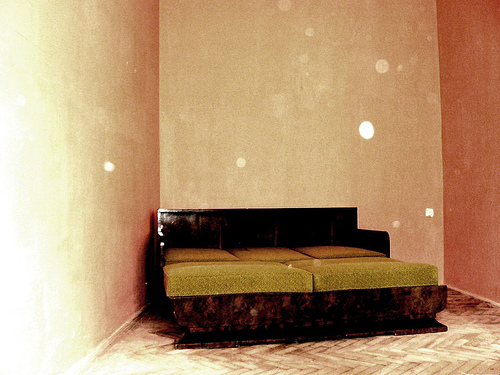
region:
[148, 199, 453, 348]
Bed in the middle of the room.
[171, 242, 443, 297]
Green cushions on bed.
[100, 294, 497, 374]
Wooden floor in the forefront.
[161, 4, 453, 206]
Brown walls in the background.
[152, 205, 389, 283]
Brown bench style headboard.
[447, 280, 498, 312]
Thin white molding on floor.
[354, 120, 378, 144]
White spot on wall.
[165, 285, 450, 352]
Dark wood colored foot board.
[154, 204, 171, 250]
Reflection of light on wood.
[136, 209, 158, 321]
Black shadow on wall.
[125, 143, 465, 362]
Bed sitting in the room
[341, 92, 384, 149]
Light reflecting on the wall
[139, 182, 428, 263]
headboard on the bed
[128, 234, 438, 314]
Mattresses on the bed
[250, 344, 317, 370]
Carpet on the ground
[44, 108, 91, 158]
The wall is smooth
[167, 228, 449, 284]
Pillows against the headboard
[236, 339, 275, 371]
The floor is patterned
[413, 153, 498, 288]
Corner in the wall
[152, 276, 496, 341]
Foot board of the bed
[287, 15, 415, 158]
floating circle white orbs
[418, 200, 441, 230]
white square on wall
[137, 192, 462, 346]
hard wood couch bed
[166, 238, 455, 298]
dark green pillow covering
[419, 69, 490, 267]
pink wall covering in a room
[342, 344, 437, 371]
wavy wood patterned floor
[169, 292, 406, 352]
dark brown wood panel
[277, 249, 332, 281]
white spots on couch cover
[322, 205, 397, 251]
dark wood frame silhouette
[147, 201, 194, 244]
light shinning on wood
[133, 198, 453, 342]
green bed in sparse room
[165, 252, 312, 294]
green upholstered cushion on daybed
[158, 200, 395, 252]
back of pull out daybed in wood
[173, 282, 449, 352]
wooden front of green bed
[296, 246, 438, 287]
green cushion on daybed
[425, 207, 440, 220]
white spot on wall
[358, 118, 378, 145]
white spot on wall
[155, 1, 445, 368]
orange wall behind bed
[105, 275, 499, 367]
wooden parquet floor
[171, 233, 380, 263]
three green upper cushions on daybed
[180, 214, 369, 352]
this is a bed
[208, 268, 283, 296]
this is the mattress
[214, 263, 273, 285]
the mattress is brown in color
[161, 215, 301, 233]
the bed is wooden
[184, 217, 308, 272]
the bed is brown in color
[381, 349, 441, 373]
this is the floor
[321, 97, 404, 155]
this is the wall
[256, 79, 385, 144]
the wall is cream in color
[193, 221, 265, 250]
the bed is black in color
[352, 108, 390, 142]
this is a mark